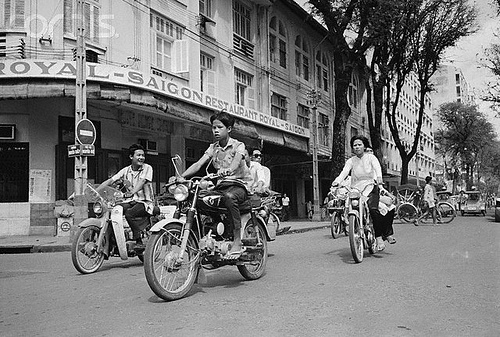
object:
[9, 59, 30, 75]
letter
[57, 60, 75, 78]
letter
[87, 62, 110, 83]
letter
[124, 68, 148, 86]
letter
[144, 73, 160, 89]
letter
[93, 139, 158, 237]
boy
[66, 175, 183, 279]
motorcycle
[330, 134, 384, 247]
woman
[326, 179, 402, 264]
motorcycle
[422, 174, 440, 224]
person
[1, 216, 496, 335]
street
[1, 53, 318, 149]
restraunt sign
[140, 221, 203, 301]
wheel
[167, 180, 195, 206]
head light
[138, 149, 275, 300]
motorcycle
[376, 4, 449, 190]
tree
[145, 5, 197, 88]
window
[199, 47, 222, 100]
window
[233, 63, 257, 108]
window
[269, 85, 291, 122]
window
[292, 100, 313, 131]
window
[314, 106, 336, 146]
window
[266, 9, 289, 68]
window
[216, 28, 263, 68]
window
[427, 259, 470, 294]
road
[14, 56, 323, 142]
sign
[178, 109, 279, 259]
boy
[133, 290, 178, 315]
shadow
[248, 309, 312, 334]
road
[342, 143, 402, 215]
person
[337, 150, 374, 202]
shirt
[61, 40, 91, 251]
post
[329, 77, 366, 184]
trunk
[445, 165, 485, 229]
trunk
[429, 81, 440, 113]
windows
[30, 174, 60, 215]
writing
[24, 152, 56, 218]
poster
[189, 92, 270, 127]
hair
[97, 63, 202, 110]
saigon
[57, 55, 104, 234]
pole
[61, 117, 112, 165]
sign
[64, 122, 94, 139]
stripe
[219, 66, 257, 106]
window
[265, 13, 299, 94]
window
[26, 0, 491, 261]
building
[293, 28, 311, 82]
window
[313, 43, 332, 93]
window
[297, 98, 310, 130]
window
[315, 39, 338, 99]
window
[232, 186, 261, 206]
bike seat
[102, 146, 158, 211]
man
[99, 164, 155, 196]
shirt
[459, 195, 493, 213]
car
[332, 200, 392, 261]
bike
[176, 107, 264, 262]
person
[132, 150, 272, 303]
bike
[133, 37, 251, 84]
buildind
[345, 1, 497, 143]
sky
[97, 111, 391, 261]
people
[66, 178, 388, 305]
bikes